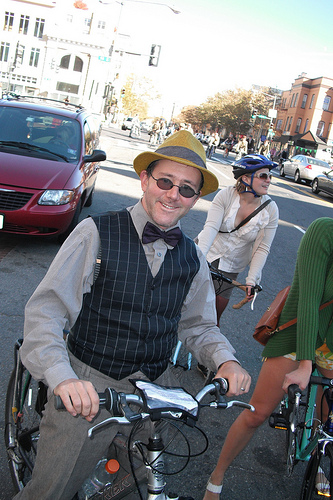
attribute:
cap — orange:
[104, 459, 120, 473]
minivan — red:
[4, 103, 94, 233]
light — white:
[249, 87, 257, 97]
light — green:
[251, 115, 256, 119]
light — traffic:
[114, 40, 196, 91]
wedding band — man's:
[239, 382, 246, 391]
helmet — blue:
[229, 152, 273, 170]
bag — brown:
[266, 279, 322, 354]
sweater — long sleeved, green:
[257, 211, 332, 363]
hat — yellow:
[118, 102, 264, 203]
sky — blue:
[180, 24, 317, 73]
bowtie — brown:
[139, 219, 182, 250]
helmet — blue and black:
[227, 140, 274, 183]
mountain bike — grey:
[4, 331, 260, 499]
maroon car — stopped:
[1, 89, 109, 251]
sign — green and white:
[95, 54, 115, 65]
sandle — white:
[198, 466, 331, 495]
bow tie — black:
[140, 221, 183, 250]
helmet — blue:
[210, 133, 272, 183]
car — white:
[281, 155, 329, 193]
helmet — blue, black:
[226, 148, 271, 203]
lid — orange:
[98, 448, 127, 481]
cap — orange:
[98, 449, 128, 477]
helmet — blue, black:
[233, 154, 278, 183]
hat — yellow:
[132, 128, 220, 197]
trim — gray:
[151, 146, 208, 172]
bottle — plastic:
[79, 455, 121, 498]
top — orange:
[105, 456, 121, 474]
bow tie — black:
[120, 219, 193, 253]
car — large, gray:
[279, 156, 331, 179]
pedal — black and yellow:
[266, 411, 289, 429]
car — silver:
[261, 109, 328, 206]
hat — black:
[134, 130, 220, 192]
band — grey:
[153, 144, 208, 170]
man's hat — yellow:
[133, 129, 218, 196]